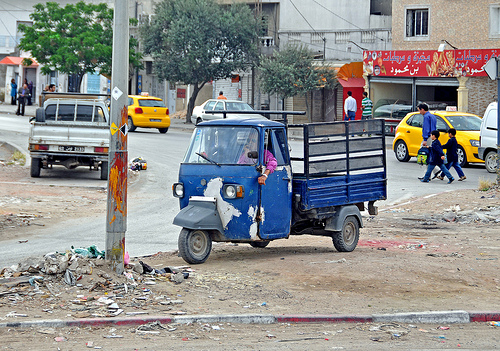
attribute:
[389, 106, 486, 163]
yellowcar — yellow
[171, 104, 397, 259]
truck — blue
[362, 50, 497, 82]
sign — red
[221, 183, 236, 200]
light — off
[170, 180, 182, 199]
light — off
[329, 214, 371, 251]
wheel — black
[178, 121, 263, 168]
windshield — clean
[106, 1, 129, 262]
pole — rusty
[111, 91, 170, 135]
taxi — yellow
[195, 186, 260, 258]
paint — peeling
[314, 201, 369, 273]
wheel — black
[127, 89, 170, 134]
cab — yellow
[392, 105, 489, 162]
cab — yellow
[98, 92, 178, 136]
taxi — yellow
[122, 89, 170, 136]
car — yellow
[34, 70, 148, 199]
truck — gray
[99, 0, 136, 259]
pole — grey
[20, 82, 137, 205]
truck — parked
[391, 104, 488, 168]
car — yellow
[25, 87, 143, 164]
truck — gray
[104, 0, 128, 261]
pole — gray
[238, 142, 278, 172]
clothes — pink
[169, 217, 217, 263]
wheel — black